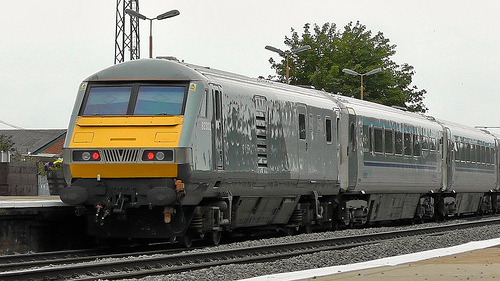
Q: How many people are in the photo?
A: None.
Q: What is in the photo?
A: A train.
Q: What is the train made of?
A: Metal.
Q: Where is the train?
A: On the tracks.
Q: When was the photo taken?
A: During the day.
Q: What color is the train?
A: Silver and yellow.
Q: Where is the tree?
A: Behind the train.